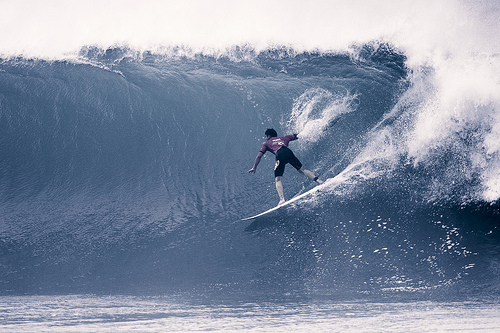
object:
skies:
[0, 0, 499, 59]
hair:
[264, 127, 276, 137]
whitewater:
[404, 7, 498, 189]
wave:
[0, 0, 499, 332]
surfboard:
[239, 176, 334, 221]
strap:
[311, 175, 320, 182]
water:
[0, 27, 498, 333]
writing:
[271, 138, 282, 145]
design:
[275, 142, 285, 147]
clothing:
[258, 135, 298, 154]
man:
[245, 127, 324, 205]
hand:
[246, 167, 257, 173]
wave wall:
[0, 40, 419, 197]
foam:
[380, 220, 388, 225]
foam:
[370, 247, 382, 254]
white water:
[289, 87, 357, 143]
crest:
[0, 24, 499, 77]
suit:
[257, 133, 305, 178]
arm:
[250, 142, 266, 170]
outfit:
[257, 134, 303, 177]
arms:
[278, 133, 302, 144]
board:
[239, 176, 341, 221]